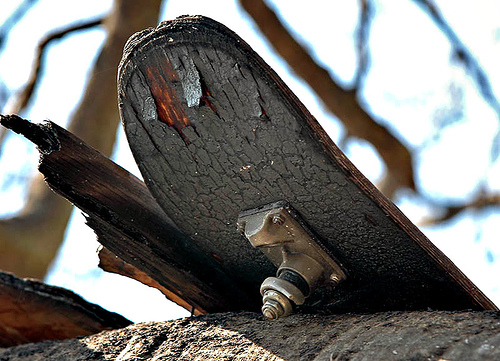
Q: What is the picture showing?
A: A skateboard.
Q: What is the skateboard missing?
A: A wheel.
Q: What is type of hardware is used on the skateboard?
A: Metal.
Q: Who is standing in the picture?
A: No one.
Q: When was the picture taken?
A: During the day.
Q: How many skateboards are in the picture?
A: None.